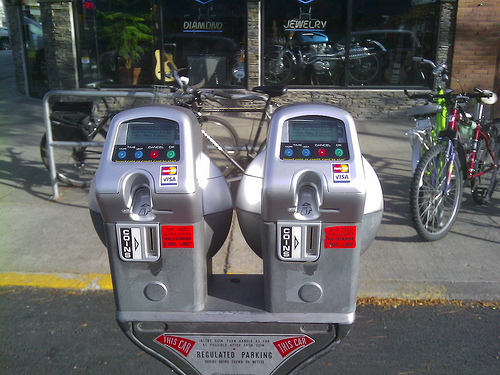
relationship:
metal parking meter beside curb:
[235, 101, 387, 314] [2, 357, 500, 374]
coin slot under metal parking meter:
[306, 226, 317, 254] [235, 101, 387, 314]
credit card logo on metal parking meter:
[330, 162, 353, 186] [235, 101, 387, 314]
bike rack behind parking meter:
[39, 87, 274, 207] [88, 101, 235, 315]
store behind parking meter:
[2, 2, 499, 122] [88, 101, 235, 315]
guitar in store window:
[154, 46, 180, 84] [74, 2, 248, 88]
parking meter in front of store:
[88, 101, 235, 315] [2, 2, 499, 122]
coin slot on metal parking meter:
[306, 226, 317, 254] [235, 101, 387, 314]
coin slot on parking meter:
[146, 224, 158, 253] [88, 101, 235, 315]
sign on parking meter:
[154, 327, 317, 375] [88, 101, 235, 315]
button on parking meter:
[117, 149, 127, 162] [88, 101, 235, 315]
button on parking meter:
[135, 149, 144, 161] [88, 101, 235, 315]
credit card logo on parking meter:
[159, 163, 181, 188] [88, 101, 235, 315]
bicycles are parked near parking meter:
[399, 52, 500, 244] [88, 101, 235, 315]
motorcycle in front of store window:
[263, 24, 388, 88] [261, 1, 440, 85]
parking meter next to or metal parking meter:
[88, 101, 235, 315] [235, 101, 387, 314]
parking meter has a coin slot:
[88, 101, 235, 315] [146, 224, 158, 253]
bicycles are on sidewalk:
[399, 52, 500, 244] [2, 47, 500, 301]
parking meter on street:
[88, 101, 235, 315] [1, 285, 498, 375]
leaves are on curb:
[357, 293, 500, 311] [2, 273, 499, 311]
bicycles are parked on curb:
[399, 52, 500, 244] [2, 273, 499, 311]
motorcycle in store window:
[263, 24, 388, 88] [261, 1, 440, 85]